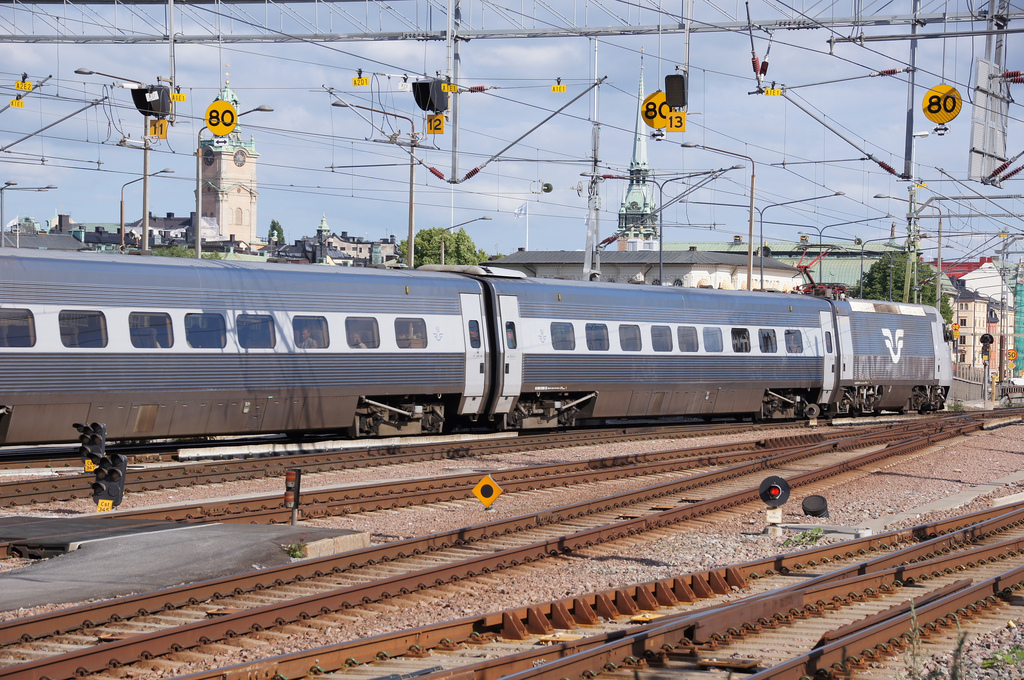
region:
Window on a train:
[1, 302, 39, 354]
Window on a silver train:
[1, 304, 40, 350]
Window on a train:
[51, 302, 113, 353]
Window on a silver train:
[54, 304, 113, 353]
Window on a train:
[122, 302, 177, 354]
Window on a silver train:
[122, 308, 177, 350]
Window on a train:
[179, 307, 230, 355]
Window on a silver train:
[181, 305, 230, 354]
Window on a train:
[232, 305, 280, 357]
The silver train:
[2, 248, 968, 427]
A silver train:
[2, 253, 949, 406]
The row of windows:
[11, 304, 446, 353]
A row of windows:
[555, 316, 816, 374]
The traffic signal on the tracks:
[61, 423, 113, 480]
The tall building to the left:
[194, 80, 286, 252]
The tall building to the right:
[611, 52, 660, 267]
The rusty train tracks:
[119, 418, 1021, 665]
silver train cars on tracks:
[5, 241, 948, 438]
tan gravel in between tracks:
[219, 417, 1022, 645]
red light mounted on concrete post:
[756, 473, 791, 540]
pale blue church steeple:
[612, 44, 664, 240]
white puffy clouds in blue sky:
[2, 7, 1021, 258]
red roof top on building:
[925, 253, 995, 283]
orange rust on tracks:
[500, 560, 747, 638]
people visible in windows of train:
[291, 309, 380, 349]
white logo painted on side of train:
[880, 320, 909, 369]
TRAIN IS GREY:
[8, 283, 922, 438]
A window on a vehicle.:
[57, 305, 109, 350]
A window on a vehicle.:
[128, 310, 173, 350]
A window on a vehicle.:
[185, 311, 230, 347]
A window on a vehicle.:
[290, 311, 332, 349]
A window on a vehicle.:
[347, 313, 382, 348]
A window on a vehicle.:
[398, 317, 428, 346]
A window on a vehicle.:
[552, 320, 576, 347]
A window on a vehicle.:
[702, 326, 723, 353]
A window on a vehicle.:
[781, 326, 804, 355]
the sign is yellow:
[206, 100, 235, 138]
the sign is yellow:
[921, 81, 960, 119]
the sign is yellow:
[649, 91, 673, 120]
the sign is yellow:
[669, 115, 683, 126]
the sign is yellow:
[476, 473, 499, 505]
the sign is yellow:
[14, 75, 35, 88]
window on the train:
[552, 319, 575, 355]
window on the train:
[620, 325, 641, 354]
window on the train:
[728, 325, 751, 354]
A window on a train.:
[544, 318, 583, 357]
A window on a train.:
[578, 323, 611, 349]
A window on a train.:
[622, 317, 649, 346]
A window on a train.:
[647, 326, 664, 353]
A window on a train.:
[680, 320, 703, 349]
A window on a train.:
[394, 313, 443, 345]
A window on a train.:
[344, 313, 389, 345]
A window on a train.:
[300, 313, 336, 343]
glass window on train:
[0, 306, 34, 351]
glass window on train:
[59, 307, 110, 345]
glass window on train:
[186, 306, 228, 351]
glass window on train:
[230, 306, 287, 352]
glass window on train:
[291, 309, 330, 349]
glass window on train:
[344, 318, 382, 348]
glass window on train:
[397, 310, 427, 348]